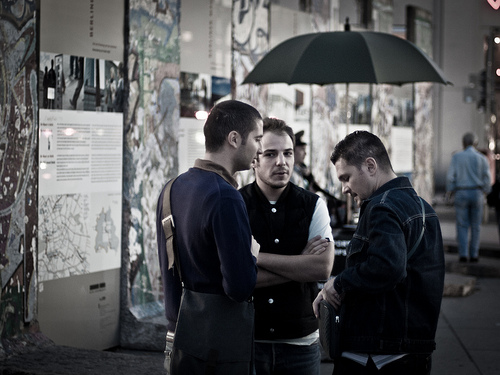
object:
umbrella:
[239, 16, 454, 88]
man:
[155, 99, 263, 373]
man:
[237, 118, 335, 374]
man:
[313, 130, 446, 374]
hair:
[204, 99, 264, 153]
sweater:
[155, 166, 259, 332]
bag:
[316, 297, 346, 362]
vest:
[237, 179, 320, 316]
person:
[445, 130, 494, 265]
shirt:
[446, 146, 492, 194]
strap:
[160, 176, 184, 282]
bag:
[170, 290, 257, 370]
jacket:
[332, 176, 446, 354]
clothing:
[444, 146, 491, 263]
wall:
[0, 0, 442, 353]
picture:
[37, 107, 124, 282]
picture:
[35, 50, 125, 114]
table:
[330, 224, 357, 277]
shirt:
[307, 197, 335, 245]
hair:
[329, 130, 394, 174]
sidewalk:
[429, 275, 499, 374]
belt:
[455, 185, 484, 192]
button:
[271, 207, 277, 213]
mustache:
[272, 167, 290, 181]